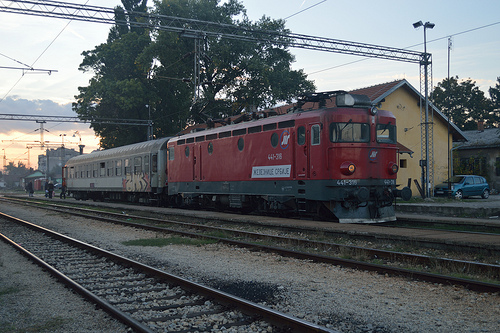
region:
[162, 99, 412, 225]
A red train engine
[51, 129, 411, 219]
A train engine and a passenger car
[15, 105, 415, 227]
A train on the tracks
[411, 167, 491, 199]
A small green car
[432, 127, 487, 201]
Green car next to yellow building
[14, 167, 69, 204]
People walking near tracks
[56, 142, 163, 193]
Passenger car of train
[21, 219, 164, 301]
Train tracks made of iron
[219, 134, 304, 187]
White sign on red train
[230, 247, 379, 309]
Gravel between railroad tracks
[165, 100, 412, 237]
red train on the tracks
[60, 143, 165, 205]
silver train car on the tracks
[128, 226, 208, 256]
patch of grass next to train tracks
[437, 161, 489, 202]
blue car parked by a building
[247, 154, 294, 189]
words on the side of the train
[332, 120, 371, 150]
window on the train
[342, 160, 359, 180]
light on the train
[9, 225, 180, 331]
train tracks on the ground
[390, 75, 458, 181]
yellow building next to the train tracks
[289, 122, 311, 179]
door on the red train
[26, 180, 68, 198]
A group of people by the tracks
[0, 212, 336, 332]
some railroad tracks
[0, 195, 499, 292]
some railroad tracks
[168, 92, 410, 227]
A large red train engine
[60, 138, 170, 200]
A grey train car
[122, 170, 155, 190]
some graffiti on a train car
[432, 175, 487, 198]
A parked blue car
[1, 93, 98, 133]
some clouds in the sky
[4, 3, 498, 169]
A clear blue sky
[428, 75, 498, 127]
the tops of some trees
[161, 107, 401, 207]
red and black train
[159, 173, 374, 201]
black bottom of train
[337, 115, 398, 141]
front windows on train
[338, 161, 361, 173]
front light on train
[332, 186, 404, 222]
safety ram on front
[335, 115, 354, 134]
black windshield wiper on train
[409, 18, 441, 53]
lights on top of pole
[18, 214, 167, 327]
metal train tracks on ground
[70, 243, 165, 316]
rocks on top of train track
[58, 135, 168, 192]
grey second train car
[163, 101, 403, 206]
Red train on railroad tracks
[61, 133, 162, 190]
Silver train on railroad tracks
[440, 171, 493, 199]
Blue car parked next to yellow building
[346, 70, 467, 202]
Yellow building next to railroad tracks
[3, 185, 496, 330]
Railroad tracks for trains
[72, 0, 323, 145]
Tall trees on side of train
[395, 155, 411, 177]
Window in yellow building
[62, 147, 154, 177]
Passenger windows of silver train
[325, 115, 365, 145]
Right windshield of red train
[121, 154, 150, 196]
Passenger entrance/exit doors